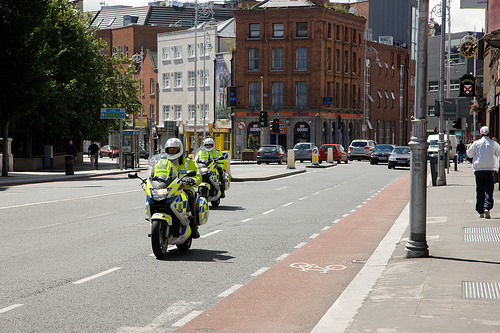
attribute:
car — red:
[318, 142, 349, 163]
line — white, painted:
[313, 189, 321, 195]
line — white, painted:
[262, 208, 273, 215]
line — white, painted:
[242, 213, 256, 222]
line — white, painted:
[200, 227, 220, 239]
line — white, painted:
[72, 266, 118, 286]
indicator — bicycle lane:
[285, 252, 345, 280]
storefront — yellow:
[184, 120, 233, 162]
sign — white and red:
[180, 120, 210, 135]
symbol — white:
[258, 249, 395, 319]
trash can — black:
[62, 144, 91, 184]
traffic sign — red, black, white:
[231, 113, 253, 137]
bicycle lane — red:
[150, 171, 409, 328]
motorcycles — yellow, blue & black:
[148, 165, 231, 268]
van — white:
[429, 133, 457, 165]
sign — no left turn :
[234, 121, 248, 131]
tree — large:
[1, 2, 145, 154]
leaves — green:
[27, 0, 141, 132]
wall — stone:
[0, 137, 86, 169]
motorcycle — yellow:
[136, 160, 193, 272]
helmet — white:
[162, 137, 182, 158]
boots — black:
[186, 216, 201, 240]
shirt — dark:
[84, 142, 102, 158]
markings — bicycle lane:
[286, 248, 346, 278]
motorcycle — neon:
[147, 170, 208, 255]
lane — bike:
[267, 221, 347, 325]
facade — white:
[163, 41, 208, 116]